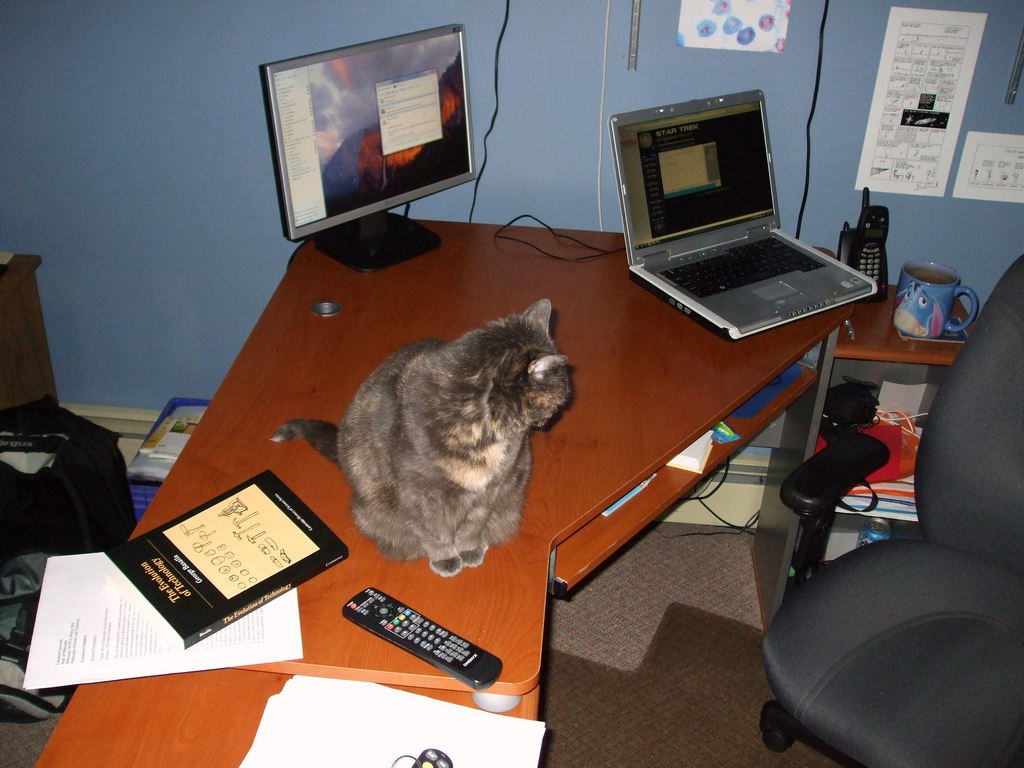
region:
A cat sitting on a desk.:
[264, 296, 574, 575]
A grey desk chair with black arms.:
[753, 250, 1016, 762]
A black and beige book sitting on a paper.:
[102, 465, 344, 646]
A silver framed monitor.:
[256, 17, 473, 267]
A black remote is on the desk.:
[339, 585, 501, 687]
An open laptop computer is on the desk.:
[604, 83, 873, 334]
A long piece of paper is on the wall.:
[848, 4, 982, 194]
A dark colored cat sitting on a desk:
[261, 311, 588, 581]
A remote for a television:
[339, 580, 513, 694]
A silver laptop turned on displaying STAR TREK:
[587, 73, 879, 353]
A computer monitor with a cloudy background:
[239, 32, 493, 271]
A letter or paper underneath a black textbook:
[18, 509, 307, 705]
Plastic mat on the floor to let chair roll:
[525, 590, 764, 765]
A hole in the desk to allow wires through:
[299, 301, 348, 320]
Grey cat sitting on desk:
[267, 295, 578, 583]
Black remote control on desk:
[339, 577, 504, 695]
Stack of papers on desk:
[229, 666, 550, 765]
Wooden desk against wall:
[29, 211, 982, 766]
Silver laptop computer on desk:
[609, 88, 881, 338]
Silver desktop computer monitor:
[252, 21, 478, 275]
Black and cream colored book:
[103, 466, 350, 659]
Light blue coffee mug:
[889, 257, 981, 349]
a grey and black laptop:
[602, 94, 866, 330]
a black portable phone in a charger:
[829, 187, 899, 304]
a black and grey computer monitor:
[254, 12, 479, 275]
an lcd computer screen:
[255, 21, 489, 241]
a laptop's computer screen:
[597, 66, 795, 253]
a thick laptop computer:
[593, 98, 872, 330]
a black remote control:
[332, 569, 511, 707]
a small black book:
[111, 476, 350, 655]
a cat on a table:
[271, 298, 592, 611]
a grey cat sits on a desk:
[269, 298, 577, 573]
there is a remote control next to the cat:
[345, 584, 505, 690]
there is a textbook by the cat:
[102, 467, 353, 648]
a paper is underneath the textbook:
[17, 554, 306, 687]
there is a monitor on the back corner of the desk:
[250, 23, 478, 273]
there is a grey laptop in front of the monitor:
[605, 88, 878, 336]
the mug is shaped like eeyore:
[892, 255, 978, 348]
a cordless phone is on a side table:
[830, 182, 898, 299]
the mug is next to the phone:
[886, 255, 981, 344]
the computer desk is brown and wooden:
[127, 214, 864, 692]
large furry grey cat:
[270, 293, 572, 581]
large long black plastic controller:
[337, 586, 511, 691]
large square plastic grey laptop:
[612, 77, 876, 349]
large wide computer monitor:
[258, 21, 489, 271]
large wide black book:
[100, 466, 358, 650]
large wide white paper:
[23, 542, 306, 698]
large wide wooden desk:
[21, 213, 974, 764]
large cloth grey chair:
[753, 252, 1023, 764]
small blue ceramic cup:
[894, 261, 980, 348]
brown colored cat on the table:
[245, 273, 584, 580]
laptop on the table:
[592, 93, 887, 362]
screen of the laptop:
[593, 96, 777, 240]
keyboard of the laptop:
[658, 236, 821, 276]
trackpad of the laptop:
[738, 276, 800, 315]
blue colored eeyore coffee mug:
[886, 248, 967, 346]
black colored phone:
[823, 165, 893, 302]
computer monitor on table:
[245, 13, 493, 289]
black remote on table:
[323, 574, 502, 695]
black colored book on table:
[100, 460, 353, 642]